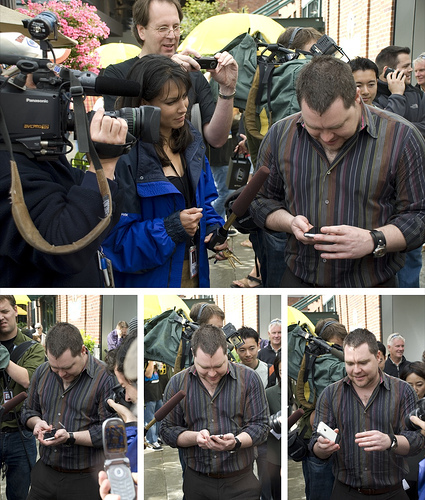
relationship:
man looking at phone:
[234, 57, 424, 287] [301, 224, 338, 241]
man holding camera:
[99, 0, 238, 148] [190, 51, 224, 71]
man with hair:
[414, 49, 424, 92] [267, 321, 276, 327]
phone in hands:
[288, 218, 388, 256] [193, 422, 244, 456]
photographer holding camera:
[22, 73, 193, 297] [22, 57, 136, 140]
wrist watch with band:
[368, 226, 388, 259] [387, 431, 400, 448]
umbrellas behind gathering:
[89, 11, 286, 68] [17, 55, 409, 279]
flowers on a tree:
[54, 8, 126, 94] [17, 0, 112, 78]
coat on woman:
[97, 141, 231, 288] [94, 53, 226, 288]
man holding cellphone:
[372, 38, 424, 123] [380, 65, 407, 89]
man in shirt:
[234, 57, 424, 287] [244, 101, 425, 287]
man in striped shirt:
[309, 328, 421, 490] [312, 378, 424, 485]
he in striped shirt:
[158, 322, 271, 498] [154, 364, 271, 467]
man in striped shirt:
[21, 322, 119, 498] [20, 353, 125, 467]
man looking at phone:
[234, 57, 424, 287] [303, 223, 334, 238]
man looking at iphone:
[309, 328, 421, 490] [312, 419, 338, 444]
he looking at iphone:
[158, 322, 271, 498] [203, 427, 226, 444]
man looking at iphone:
[21, 322, 119, 498] [39, 425, 61, 442]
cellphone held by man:
[102, 415, 136, 498] [15, 320, 130, 499]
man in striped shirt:
[15, 320, 130, 499] [20, 353, 125, 467]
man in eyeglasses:
[99, 0, 238, 148] [148, 23, 184, 38]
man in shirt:
[99, 0, 238, 148] [244, 101, 423, 283]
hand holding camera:
[84, 111, 131, 185] [0, 12, 167, 286]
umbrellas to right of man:
[168, 11, 285, 66] [99, 0, 238, 148]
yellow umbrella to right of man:
[87, 40, 142, 69] [2, 68, 126, 287]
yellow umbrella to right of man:
[143, 295, 194, 323] [2, 68, 126, 287]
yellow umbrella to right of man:
[288, 305, 317, 337] [234, 57, 424, 287]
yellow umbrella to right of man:
[11, 294, 30, 304] [21, 322, 119, 498]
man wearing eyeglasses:
[99, 0, 238, 148] [148, 23, 184, 38]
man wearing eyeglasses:
[2, 68, 126, 287] [148, 23, 184, 38]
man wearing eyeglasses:
[234, 57, 424, 287] [148, 23, 184, 38]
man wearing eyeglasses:
[21, 322, 119, 498] [148, 23, 184, 38]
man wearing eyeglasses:
[0, 295, 44, 498] [148, 23, 184, 38]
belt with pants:
[339, 480, 400, 493] [331, 482, 410, 498]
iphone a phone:
[42, 427, 57, 442] [303, 223, 334, 238]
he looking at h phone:
[162, 339, 266, 500] [303, 226, 329, 238]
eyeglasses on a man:
[148, 23, 184, 38] [99, 0, 238, 148]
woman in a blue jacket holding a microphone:
[101, 48, 239, 290] [200, 163, 271, 246]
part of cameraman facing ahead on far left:
[103, 45, 116, 102] [7, 190, 71, 285]